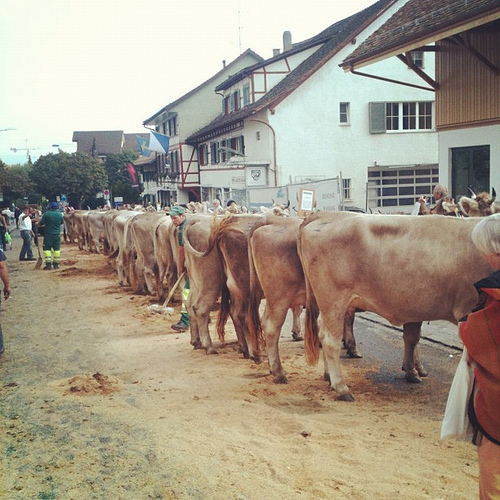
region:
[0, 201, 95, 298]
crowd of people standing behind cows.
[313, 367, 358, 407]
Hoof on the back end of a cow's leg.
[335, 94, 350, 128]
Second story window on a two story home.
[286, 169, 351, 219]
Large structure with a sign posted to it.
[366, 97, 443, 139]
Set of three windows on the second story of a building.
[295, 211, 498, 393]
Large brown cow standing in front of a building.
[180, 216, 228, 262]
Tale on the back end of a cow.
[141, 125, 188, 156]
blue and white flag on a building.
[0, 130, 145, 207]
Group of trees outside of a building.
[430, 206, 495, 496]
Person with gray hair holding a bag.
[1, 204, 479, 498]
sand spread over pavement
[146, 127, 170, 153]
blue and white flag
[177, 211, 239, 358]
back end of cow with tail swishing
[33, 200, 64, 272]
person holding a shovel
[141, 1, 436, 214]
white building with several windows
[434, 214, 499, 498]
woman holding a bag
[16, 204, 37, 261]
man pointing at something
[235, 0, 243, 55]
antenna on rooftop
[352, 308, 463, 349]
sidewalk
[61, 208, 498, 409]
long line of cows in street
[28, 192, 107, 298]
Man with back turned in green shirt and pants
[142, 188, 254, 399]
man in green walking between cows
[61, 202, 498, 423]
cows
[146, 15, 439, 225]
all white house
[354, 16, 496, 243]
closest house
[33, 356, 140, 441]
pile of dirt behind cows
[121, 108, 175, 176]
blue and white diagonal flag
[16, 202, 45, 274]
man in white shirt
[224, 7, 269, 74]
pole on top of house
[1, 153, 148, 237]
trees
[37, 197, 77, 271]
the man wears green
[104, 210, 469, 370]
cows standing in line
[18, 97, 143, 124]
the sky is white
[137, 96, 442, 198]
the building is wide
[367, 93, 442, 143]
the building has windows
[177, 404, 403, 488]
there is dirt on the ground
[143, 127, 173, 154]
the flag is blue and white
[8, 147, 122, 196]
the tree is green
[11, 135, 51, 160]
the crane is in the background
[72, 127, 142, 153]
the roof is black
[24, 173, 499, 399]
many brown cows stand in a row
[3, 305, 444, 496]
sawdust and cow manure cover the ground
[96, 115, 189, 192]
three flags on the side of a building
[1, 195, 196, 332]
men in green clean up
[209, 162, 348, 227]
a chain link fence by the buildings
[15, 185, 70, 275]
man in green with a shovel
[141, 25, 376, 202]
two large white buildings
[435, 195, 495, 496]
woman looking at cows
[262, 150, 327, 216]
a small sign in front of the cows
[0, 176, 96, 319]
people wander around near the cows